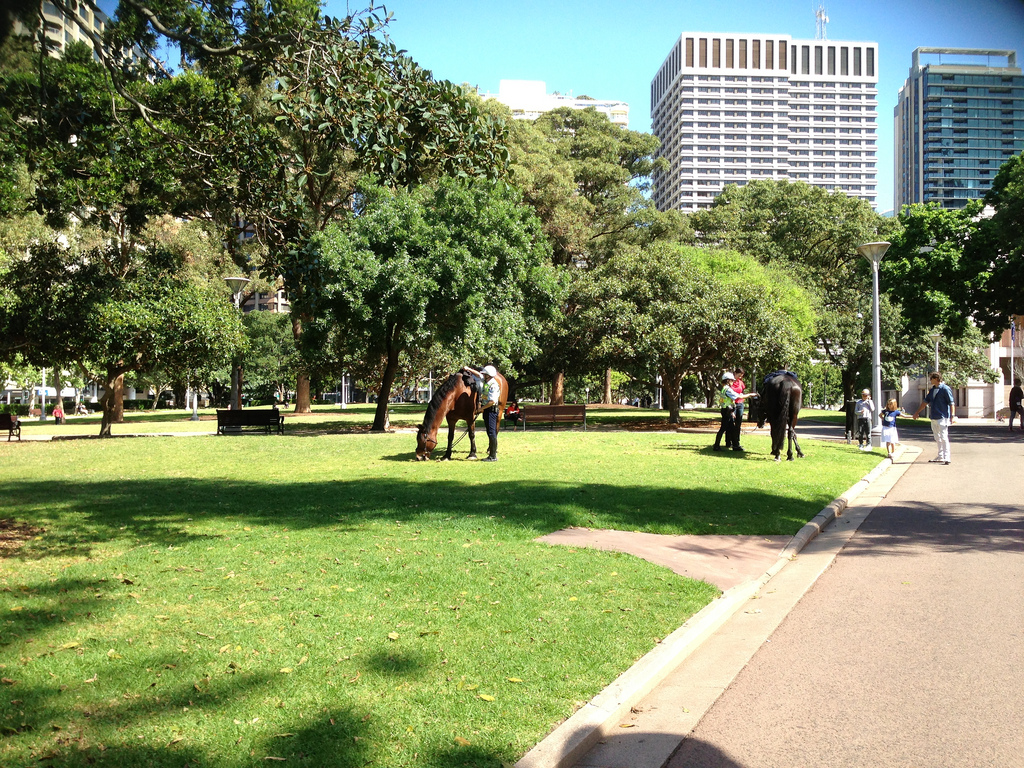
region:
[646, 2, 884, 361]
large building behind trees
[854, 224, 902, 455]
kids standing under light post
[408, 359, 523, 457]
a horse in the park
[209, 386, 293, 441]
a wooden bench near the walk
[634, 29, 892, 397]
a tall city building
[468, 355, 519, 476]
a man near a horse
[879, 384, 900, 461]
a child walking on a curb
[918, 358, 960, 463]
a man in white pants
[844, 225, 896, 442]
a tall lamp post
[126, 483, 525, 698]
grass in the park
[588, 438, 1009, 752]
an asphalt walk way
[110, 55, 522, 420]
trees in a city park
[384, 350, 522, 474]
Rider and his horse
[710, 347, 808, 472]
Dismounted rider and horse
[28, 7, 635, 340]
Varieties of trees with green foliage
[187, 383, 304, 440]
Bench under tree in shade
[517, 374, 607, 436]
Bench under tree in shade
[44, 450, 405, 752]
Lawn with shady areas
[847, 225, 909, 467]
Two kids in front of street lamp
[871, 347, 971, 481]
Adult with child wearing blue and white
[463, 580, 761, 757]
Curb separating lawn and road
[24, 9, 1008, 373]
Buildings behind trees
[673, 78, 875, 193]
Many windows on a white building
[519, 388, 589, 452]
A park bench in the distance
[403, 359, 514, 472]
A horse eating the grass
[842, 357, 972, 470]
People in the background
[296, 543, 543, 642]
Grass is green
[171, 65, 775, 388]
Many trees in the background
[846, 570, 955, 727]
Pavement is gray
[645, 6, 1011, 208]
Two buildings next to each other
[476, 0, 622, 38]
Sky is bright blue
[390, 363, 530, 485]
A horse is brown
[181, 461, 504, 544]
Shadows on the grass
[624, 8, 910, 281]
A tall white building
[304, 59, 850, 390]
Many bushy trees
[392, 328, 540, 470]
A man and his horse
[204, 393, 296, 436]
A park bench in the distance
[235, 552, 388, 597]
Grass is very green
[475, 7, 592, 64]
Sky is bright blue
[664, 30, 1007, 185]
Many windows on buildings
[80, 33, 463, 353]
Trees with green leaves.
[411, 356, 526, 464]
Brown horse eating grass.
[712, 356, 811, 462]
Two people standing next to a horse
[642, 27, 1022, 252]
Tall modern buildings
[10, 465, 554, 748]
Well maintained green grass.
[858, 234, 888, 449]
Light post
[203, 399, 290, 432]
Shaded park bench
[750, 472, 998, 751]
Paved walkway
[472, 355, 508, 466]
Person standing next to a horse.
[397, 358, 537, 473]
Horse eating in the grass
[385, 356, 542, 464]
Man standing next to horse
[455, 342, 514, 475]
Man wearing white hat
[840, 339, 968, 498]
Man holding little girl's hand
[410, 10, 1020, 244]
Three buildings in the distance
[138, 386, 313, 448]
Bench sitting under tree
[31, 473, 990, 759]
Shadow of trees reflecting off ground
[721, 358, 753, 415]
Man wearing red shirt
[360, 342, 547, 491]
Man holding horse by leash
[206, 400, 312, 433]
bench on the grass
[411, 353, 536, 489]
horse in park-like area